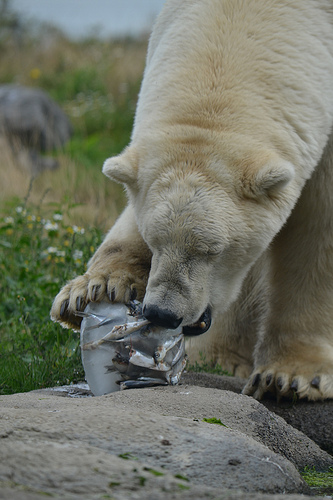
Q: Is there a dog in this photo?
A: No, there are no dogs.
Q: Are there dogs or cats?
A: No, there are no dogs or cats.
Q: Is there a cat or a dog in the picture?
A: No, there are no dogs or cats.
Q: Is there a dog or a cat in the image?
A: No, there are no dogs or cats.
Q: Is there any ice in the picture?
A: Yes, there is ice.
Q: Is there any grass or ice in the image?
A: Yes, there is ice.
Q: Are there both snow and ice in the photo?
A: No, there is ice but no snow.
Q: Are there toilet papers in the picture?
A: No, there are no toilet papers.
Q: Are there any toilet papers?
A: No, there are no toilet papers.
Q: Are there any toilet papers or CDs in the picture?
A: No, there are no toilet papers or cds.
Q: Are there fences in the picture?
A: No, there are no fences.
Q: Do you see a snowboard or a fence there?
A: No, there are no fences or snowboards.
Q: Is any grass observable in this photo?
A: Yes, there is grass.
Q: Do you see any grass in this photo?
A: Yes, there is grass.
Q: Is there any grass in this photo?
A: Yes, there is grass.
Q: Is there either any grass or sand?
A: Yes, there is grass.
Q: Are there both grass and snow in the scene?
A: No, there is grass but no snow.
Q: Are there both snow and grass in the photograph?
A: No, there is grass but no snow.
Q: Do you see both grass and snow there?
A: No, there is grass but no snow.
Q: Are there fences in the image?
A: No, there are no fences.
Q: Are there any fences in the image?
A: No, there are no fences.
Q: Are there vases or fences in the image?
A: No, there are no fences or vases.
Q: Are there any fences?
A: No, there are no fences.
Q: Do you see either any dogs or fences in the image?
A: No, there are no fences or dogs.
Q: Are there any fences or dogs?
A: No, there are no fences or dogs.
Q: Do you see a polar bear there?
A: Yes, there is a polar bear.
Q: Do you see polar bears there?
A: Yes, there is a polar bear.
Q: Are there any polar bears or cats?
A: Yes, there is a polar bear.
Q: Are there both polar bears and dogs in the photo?
A: No, there is a polar bear but no dogs.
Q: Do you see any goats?
A: No, there are no goats.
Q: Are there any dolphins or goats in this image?
A: No, there are no goats or dolphins.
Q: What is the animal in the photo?
A: The animal is a polar bear.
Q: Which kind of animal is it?
A: The animal is a polar bear.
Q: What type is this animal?
A: This is a polar bear.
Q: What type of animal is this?
A: This is a polar bear.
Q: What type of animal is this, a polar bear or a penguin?
A: This is a polar bear.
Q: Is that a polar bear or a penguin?
A: That is a polar bear.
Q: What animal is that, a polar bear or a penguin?
A: That is a polar bear.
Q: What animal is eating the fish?
A: The polar bear is eating the fish.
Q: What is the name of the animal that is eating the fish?
A: The animal is a polar bear.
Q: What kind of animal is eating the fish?
A: The animal is a polar bear.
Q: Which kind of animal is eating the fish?
A: The animal is a polar bear.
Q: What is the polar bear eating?
A: The polar bear is eating fish.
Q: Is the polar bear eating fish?
A: Yes, the polar bear is eating fish.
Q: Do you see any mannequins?
A: No, there are no mannequins.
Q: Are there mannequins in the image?
A: No, there are no mannequins.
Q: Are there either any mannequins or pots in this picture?
A: No, there are no mannequins or pots.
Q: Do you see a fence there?
A: No, there are no fences.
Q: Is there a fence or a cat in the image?
A: No, there are no fences or cats.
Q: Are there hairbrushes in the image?
A: No, there are no hairbrushes.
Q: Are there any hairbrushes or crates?
A: No, there are no hairbrushes or crates.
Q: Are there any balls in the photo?
A: No, there are no balls.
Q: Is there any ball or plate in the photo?
A: No, there are no balls or plates.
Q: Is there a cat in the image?
A: No, there are no cats.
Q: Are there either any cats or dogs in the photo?
A: No, there are no cats or dogs.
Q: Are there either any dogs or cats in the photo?
A: No, there are no cats or dogs.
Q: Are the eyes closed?
A: Yes, the eyes are closed.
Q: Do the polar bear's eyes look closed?
A: Yes, the eyes are closed.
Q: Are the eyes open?
A: No, the eyes are closed.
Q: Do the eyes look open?
A: No, the eyes are closed.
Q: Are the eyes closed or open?
A: The eyes are closed.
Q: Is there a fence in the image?
A: No, there are no fences.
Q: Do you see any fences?
A: No, there are no fences.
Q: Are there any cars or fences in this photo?
A: No, there are no fences or cars.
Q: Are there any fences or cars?
A: No, there are no fences or cars.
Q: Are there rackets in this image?
A: No, there are no rackets.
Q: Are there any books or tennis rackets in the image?
A: No, there are no tennis rackets or books.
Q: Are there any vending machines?
A: No, there are no vending machines.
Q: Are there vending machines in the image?
A: No, there are no vending machines.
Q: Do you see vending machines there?
A: No, there are no vending machines.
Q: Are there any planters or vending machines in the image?
A: No, there are no vending machines or planters.